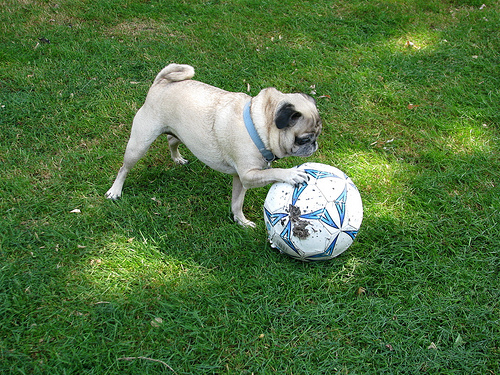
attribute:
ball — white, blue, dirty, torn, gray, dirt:
[271, 160, 359, 261]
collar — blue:
[237, 91, 271, 154]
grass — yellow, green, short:
[353, 44, 385, 97]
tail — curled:
[149, 53, 194, 80]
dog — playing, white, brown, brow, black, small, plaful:
[87, 52, 326, 178]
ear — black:
[265, 97, 297, 125]